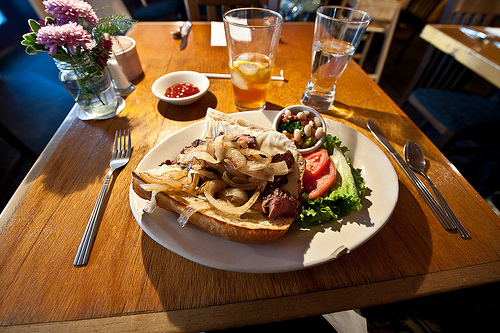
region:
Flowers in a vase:
[18, 0, 136, 124]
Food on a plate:
[127, 101, 403, 277]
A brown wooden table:
[1, 17, 499, 330]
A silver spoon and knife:
[364, 112, 474, 244]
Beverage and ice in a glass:
[222, 4, 285, 113]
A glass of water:
[301, 2, 375, 114]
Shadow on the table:
[21, 107, 141, 200]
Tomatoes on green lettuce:
[297, 144, 372, 233]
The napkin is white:
[207, 16, 254, 50]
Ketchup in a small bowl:
[149, 66, 212, 109]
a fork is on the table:
[76, 124, 135, 271]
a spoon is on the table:
[401, 140, 479, 250]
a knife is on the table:
[366, 120, 464, 238]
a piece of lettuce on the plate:
[290, 133, 358, 237]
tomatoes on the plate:
[298, 150, 343, 193]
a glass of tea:
[227, 8, 278, 105]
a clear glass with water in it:
[305, 8, 372, 105]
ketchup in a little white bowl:
[159, 70, 201, 108]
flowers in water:
[37, 25, 139, 120]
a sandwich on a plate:
[171, 103, 363, 260]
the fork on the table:
[72, 128, 131, 265]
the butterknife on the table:
[364, 117, 456, 231]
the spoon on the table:
[403, 138, 471, 240]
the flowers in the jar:
[20, 0, 137, 116]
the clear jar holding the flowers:
[53, 54, 118, 116]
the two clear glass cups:
[222, 6, 371, 111]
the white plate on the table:
[128, 108, 398, 273]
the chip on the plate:
[331, 245, 348, 260]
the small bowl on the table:
[150, 69, 209, 105]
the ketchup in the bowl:
[163, 82, 200, 99]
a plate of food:
[83, 36, 478, 278]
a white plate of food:
[116, 71, 496, 264]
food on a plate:
[71, 43, 443, 322]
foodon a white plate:
[49, 52, 494, 275]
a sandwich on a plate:
[118, 103, 498, 258]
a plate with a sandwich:
[86, 104, 421, 289]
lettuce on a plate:
[64, 83, 409, 265]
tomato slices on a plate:
[183, 104, 499, 325]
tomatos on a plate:
[149, 86, 417, 327]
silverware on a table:
[328, 93, 498, 286]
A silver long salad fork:
[72, 123, 132, 268]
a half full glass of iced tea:
[221, 0, 279, 108]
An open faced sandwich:
[127, 109, 306, 241]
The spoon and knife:
[362, 112, 466, 242]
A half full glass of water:
[297, 2, 371, 112]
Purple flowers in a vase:
[18, 0, 140, 125]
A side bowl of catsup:
[150, 64, 211, 107]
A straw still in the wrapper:
[184, 72, 283, 80]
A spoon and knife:
[166, 20, 197, 49]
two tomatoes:
[300, 149, 335, 199]